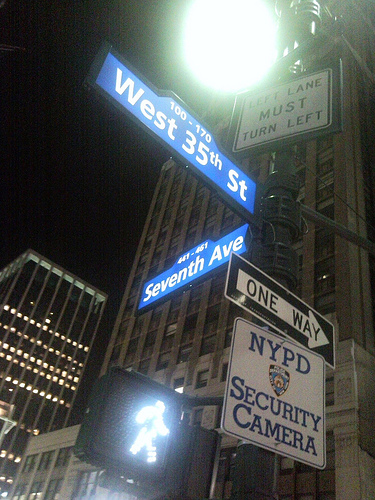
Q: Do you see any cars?
A: No, there are no cars.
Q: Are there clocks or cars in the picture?
A: No, there are no cars or clocks.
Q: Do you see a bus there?
A: No, there are no buses.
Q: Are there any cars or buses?
A: No, there are no buses or cars.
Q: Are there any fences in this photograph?
A: No, there are no fences.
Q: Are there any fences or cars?
A: No, there are no fences or cars.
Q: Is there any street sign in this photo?
A: Yes, there is a street sign.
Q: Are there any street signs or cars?
A: Yes, there is a street sign.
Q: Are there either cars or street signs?
A: Yes, there is a street sign.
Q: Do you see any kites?
A: No, there are no kites.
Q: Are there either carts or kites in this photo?
A: No, there are no kites or carts.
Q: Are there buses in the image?
A: No, there are no buses.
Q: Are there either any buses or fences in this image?
A: No, there are no buses or fences.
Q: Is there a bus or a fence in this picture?
A: No, there are no buses or fences.